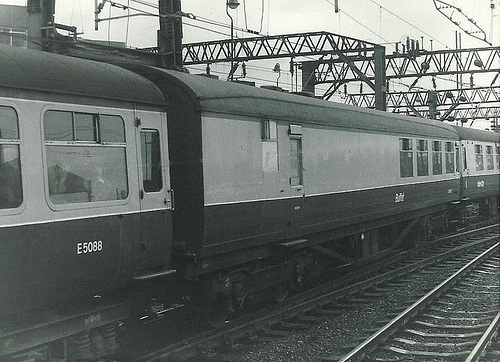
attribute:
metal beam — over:
[393, 105, 498, 123]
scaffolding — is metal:
[137, 30, 498, 132]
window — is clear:
[44, 114, 129, 207]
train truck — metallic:
[168, 70, 467, 279]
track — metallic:
[356, 228, 498, 348]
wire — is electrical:
[124, 0, 249, 35]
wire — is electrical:
[364, 0, 449, 53]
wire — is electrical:
[324, 0, 407, 53]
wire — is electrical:
[90, 4, 245, 48]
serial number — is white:
[76, 237, 106, 255]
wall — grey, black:
[208, 112, 233, 144]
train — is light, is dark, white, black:
[2, 45, 498, 306]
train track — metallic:
[243, 292, 350, 357]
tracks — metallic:
[333, 239, 498, 359]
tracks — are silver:
[379, 275, 482, 337]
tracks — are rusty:
[393, 221, 498, 315]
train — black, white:
[0, 56, 497, 356]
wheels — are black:
[0, 189, 494, 356]